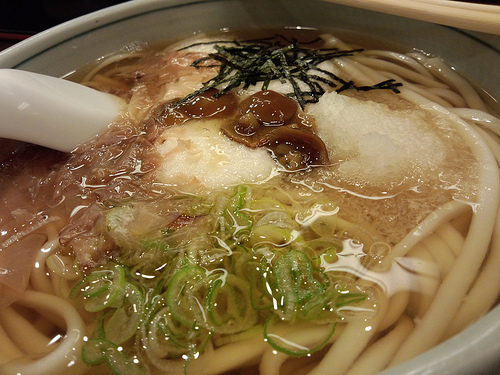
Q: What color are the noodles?
A: White.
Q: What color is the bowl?
A: White and black.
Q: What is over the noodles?
A: Broth.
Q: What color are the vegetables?
A: Green.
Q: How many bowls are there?
A: One.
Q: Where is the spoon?
A: In the soup.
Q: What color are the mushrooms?
A: Brown.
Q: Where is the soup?
A: In the bowl.